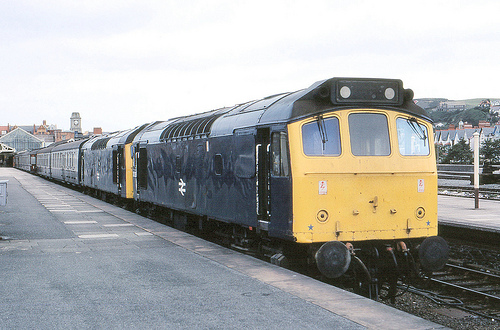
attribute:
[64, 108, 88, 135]
tower — building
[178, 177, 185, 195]
symbol — yellow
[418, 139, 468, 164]
ground — metal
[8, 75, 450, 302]
train — black, yellow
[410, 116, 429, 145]
windshield wiper — black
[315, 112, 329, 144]
windshield wiper — black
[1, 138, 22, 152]
metal — white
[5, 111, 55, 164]
building — distant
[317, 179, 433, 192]
stickers — white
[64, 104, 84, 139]
spire — gray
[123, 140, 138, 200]
divider — yellow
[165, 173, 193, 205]
symbol — white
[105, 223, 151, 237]
rectangle — white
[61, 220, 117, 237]
rectangle — white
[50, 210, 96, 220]
rectangle — white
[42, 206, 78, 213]
rectangle — white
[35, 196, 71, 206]
rectangle — white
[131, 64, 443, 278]
train car — black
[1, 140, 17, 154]
piece — metal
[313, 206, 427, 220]
indents — circular